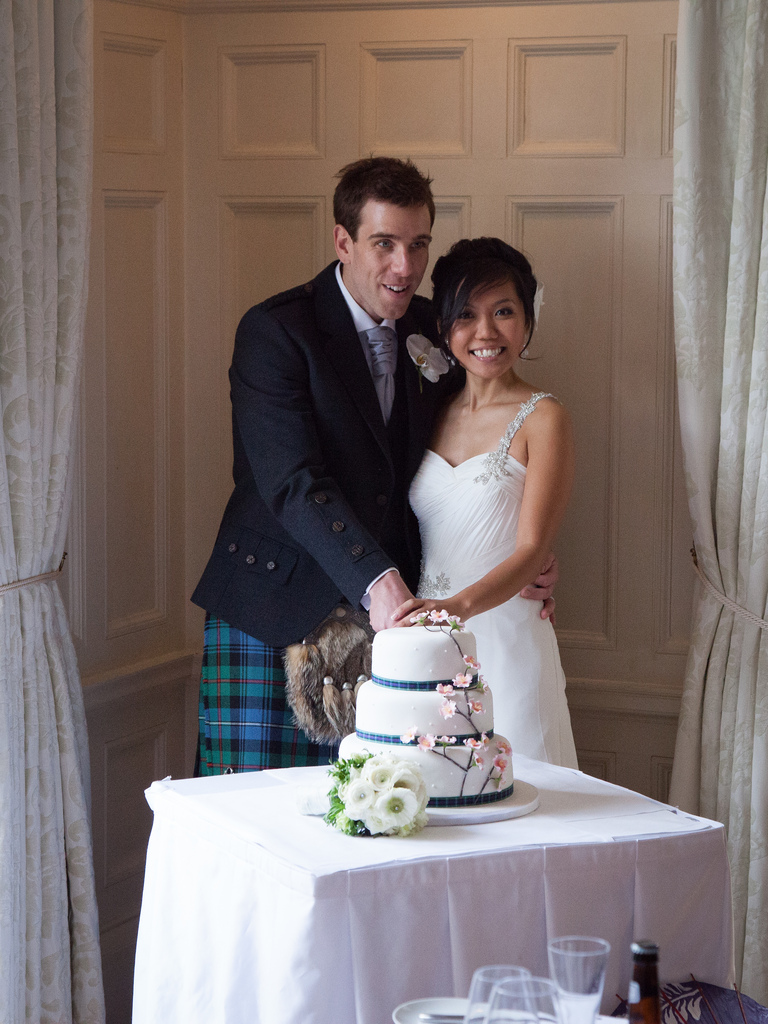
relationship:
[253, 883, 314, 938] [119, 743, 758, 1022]
light on cloth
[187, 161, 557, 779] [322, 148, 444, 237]
groom has hair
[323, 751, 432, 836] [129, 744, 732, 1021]
bouquet on cloth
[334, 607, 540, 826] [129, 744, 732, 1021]
cake on cloth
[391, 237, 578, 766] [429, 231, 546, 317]
woman has hair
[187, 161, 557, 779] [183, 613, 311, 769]
groom has kilt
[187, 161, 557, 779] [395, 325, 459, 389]
groom wears flower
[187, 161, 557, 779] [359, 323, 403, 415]
groom wears tie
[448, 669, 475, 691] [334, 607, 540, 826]
flower on cake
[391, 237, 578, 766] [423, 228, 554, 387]
woman has head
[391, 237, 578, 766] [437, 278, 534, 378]
woman has face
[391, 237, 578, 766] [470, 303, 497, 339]
woman has nose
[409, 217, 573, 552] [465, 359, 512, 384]
woman has chin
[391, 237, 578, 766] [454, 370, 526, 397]
woman has neck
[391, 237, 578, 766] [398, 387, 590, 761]
woman wears dress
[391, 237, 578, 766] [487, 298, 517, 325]
woman has eye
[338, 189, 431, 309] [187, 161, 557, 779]
head on groom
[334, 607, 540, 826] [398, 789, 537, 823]
cake on tray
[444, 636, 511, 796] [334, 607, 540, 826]
flowers on cake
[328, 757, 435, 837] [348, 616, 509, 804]
bouquet near cake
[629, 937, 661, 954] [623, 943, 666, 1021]
opener of bottle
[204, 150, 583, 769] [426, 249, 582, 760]
couple by cake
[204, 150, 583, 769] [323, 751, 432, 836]
couple by bouquet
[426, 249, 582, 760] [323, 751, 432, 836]
cake by bouquet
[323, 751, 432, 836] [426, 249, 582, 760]
bouquet by cake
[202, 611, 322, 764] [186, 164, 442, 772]
kilt on groom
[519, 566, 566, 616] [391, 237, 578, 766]
arm on woman